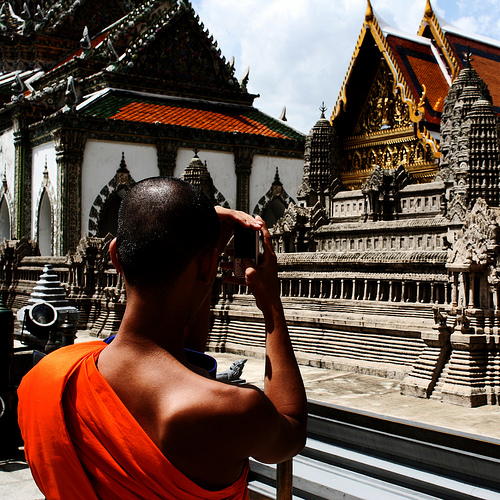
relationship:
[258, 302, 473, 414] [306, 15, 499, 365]
step of temple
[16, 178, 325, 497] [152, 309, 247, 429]
man has skin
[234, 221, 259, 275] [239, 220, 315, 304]
camera in hand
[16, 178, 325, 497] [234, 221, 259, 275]
man with camera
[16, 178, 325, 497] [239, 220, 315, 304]
man has hand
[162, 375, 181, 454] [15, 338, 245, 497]
bone in back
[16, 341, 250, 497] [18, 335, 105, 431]
clothing covering shoulder